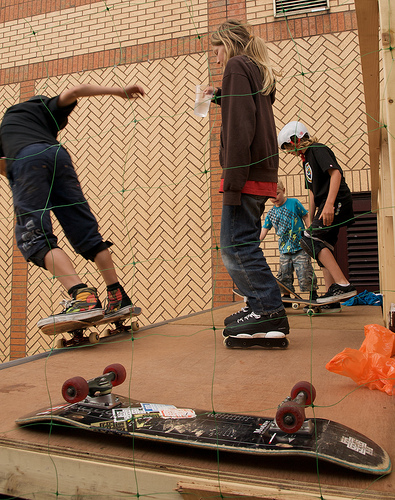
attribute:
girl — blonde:
[198, 29, 303, 336]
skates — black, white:
[220, 293, 289, 351]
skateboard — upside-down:
[16, 364, 388, 475]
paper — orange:
[328, 322, 394, 405]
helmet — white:
[278, 119, 306, 142]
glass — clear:
[194, 81, 212, 118]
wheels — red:
[62, 361, 318, 435]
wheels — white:
[231, 335, 289, 347]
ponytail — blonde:
[210, 18, 280, 93]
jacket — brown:
[215, 56, 282, 182]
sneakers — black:
[315, 283, 357, 305]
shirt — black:
[303, 148, 349, 200]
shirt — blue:
[263, 200, 310, 252]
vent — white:
[266, 0, 336, 21]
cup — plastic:
[193, 85, 216, 126]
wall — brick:
[3, 0, 205, 80]